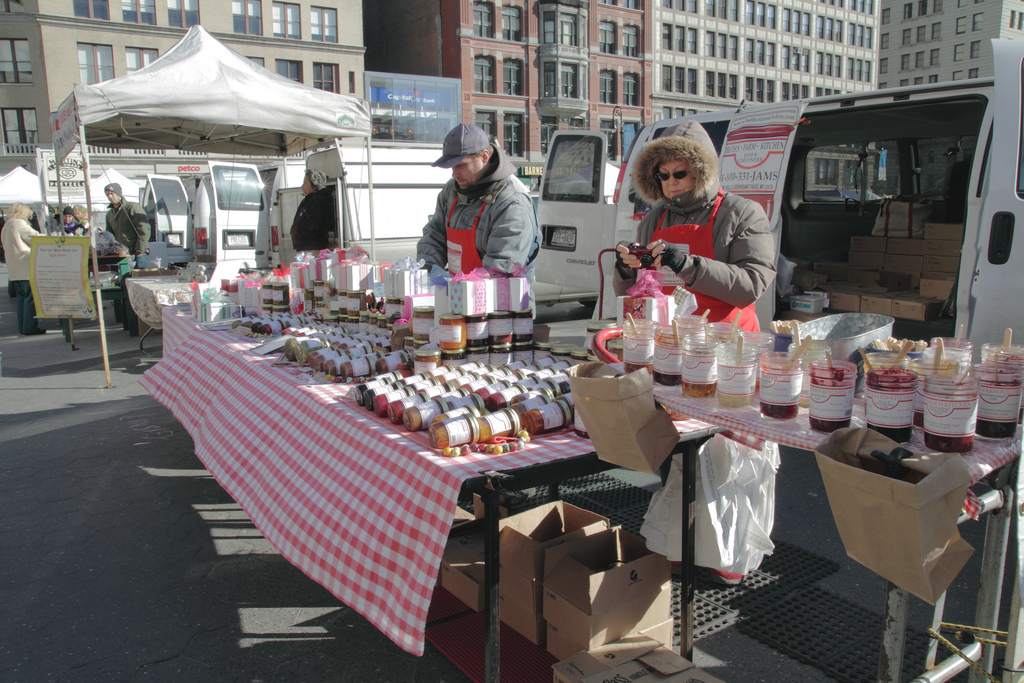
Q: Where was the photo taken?
A: At a market.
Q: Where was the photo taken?
A: Maybe at a festival.